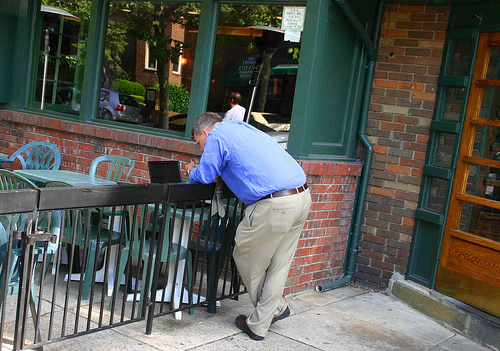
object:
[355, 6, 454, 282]
wall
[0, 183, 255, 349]
fence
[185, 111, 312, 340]
man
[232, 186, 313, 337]
khaki pants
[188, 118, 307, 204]
blue shirt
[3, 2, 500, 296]
building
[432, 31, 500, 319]
door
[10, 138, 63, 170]
chairs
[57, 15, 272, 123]
reflection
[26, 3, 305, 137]
glass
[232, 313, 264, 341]
shoes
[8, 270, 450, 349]
cement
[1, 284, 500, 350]
ground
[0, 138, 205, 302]
furniture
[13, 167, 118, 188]
table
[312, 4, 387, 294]
gutter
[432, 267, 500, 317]
kick plate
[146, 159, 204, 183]
laptop